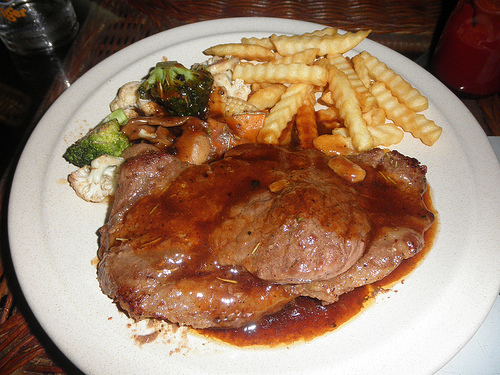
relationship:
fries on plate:
[203, 25, 443, 152] [7, 19, 500, 375]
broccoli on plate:
[136, 61, 211, 116] [7, 19, 500, 375]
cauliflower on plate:
[67, 155, 124, 201] [7, 19, 500, 375]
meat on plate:
[99, 143, 434, 324] [7, 19, 500, 375]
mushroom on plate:
[126, 115, 191, 148] [7, 19, 500, 375]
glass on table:
[0, 0, 79, 50] [1, 2, 499, 132]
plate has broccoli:
[7, 19, 500, 375] [136, 61, 211, 116]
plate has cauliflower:
[7, 19, 500, 375] [67, 155, 124, 201]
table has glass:
[1, 2, 499, 132] [0, 0, 79, 50]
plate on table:
[7, 19, 500, 375] [1, 2, 499, 132]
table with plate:
[1, 2, 499, 132] [7, 19, 500, 375]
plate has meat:
[7, 19, 500, 375] [99, 143, 434, 324]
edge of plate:
[116, 16, 315, 35] [7, 19, 500, 375]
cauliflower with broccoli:
[67, 155, 124, 201] [136, 61, 211, 116]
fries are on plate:
[203, 25, 443, 152] [7, 19, 500, 375]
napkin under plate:
[493, 136, 499, 151] [7, 19, 500, 375]